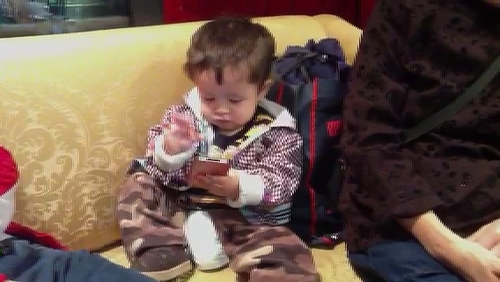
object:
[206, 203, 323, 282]
pants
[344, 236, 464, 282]
blue pants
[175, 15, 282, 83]
hair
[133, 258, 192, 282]
brown shoe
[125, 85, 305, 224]
coat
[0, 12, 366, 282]
brown chair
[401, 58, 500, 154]
strap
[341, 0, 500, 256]
shirt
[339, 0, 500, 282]
adult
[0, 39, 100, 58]
light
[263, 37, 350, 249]
backpack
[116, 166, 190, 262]
pants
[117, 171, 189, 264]
camo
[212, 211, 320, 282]
camo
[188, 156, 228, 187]
cell phone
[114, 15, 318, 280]
baby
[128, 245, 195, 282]
shoe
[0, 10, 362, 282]
sofa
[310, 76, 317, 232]
line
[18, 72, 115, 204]
print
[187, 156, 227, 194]
phone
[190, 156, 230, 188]
cell